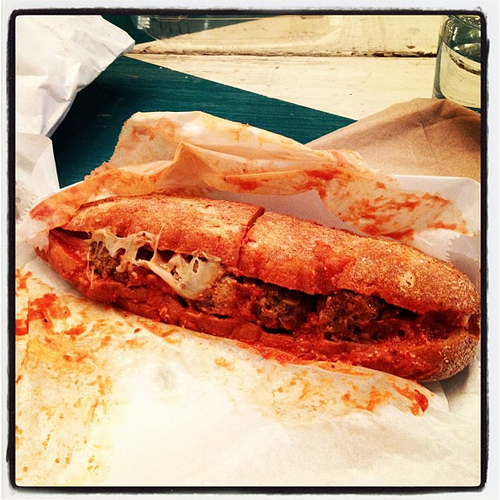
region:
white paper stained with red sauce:
[45, 95, 462, 236]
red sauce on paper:
[17, 299, 199, 451]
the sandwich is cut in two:
[36, 190, 483, 400]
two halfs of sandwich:
[31, 188, 481, 389]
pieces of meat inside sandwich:
[83, 242, 389, 342]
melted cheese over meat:
[90, 223, 231, 300]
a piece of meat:
[324, 288, 379, 348]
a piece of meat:
[248, 285, 306, 336]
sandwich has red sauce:
[68, 318, 440, 379]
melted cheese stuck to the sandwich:
[90, 219, 222, 294]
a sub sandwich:
[18, 178, 483, 403]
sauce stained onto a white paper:
[22, 91, 482, 483]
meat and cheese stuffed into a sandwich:
[51, 213, 461, 364]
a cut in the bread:
[222, 203, 293, 273]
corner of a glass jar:
[434, 15, 482, 118]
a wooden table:
[47, 18, 482, 179]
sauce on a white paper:
[18, 280, 448, 475]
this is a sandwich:
[35, 125, 454, 450]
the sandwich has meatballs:
[51, 177, 478, 424]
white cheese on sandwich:
[94, 213, 250, 310]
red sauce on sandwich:
[83, 201, 373, 390]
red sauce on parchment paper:
[22, 287, 169, 451]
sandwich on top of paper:
[52, 131, 457, 498]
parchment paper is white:
[62, 110, 443, 488]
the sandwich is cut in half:
[43, 145, 497, 422]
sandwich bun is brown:
[110, 178, 445, 320]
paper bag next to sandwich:
[282, 75, 474, 204]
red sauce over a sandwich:
[22, 180, 482, 380]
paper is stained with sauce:
[82, 105, 437, 210]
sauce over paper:
[16, 295, 102, 425]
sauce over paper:
[255, 370, 435, 435]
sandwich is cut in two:
[40, 186, 480, 381]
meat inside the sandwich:
[67, 228, 433, 359]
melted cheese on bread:
[82, 221, 224, 308]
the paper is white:
[21, 20, 133, 125]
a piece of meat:
[308, 293, 379, 344]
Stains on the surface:
[361, 47, 430, 62]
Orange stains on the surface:
[25, 293, 102, 363]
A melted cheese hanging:
[92, 227, 167, 272]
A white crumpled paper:
[350, 396, 467, 470]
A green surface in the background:
[108, 78, 193, 108]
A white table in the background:
[283, 67, 390, 90]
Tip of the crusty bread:
[442, 354, 474, 390]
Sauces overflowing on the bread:
[280, 315, 429, 380]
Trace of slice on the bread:
[240, 200, 282, 239]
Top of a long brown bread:
[351, 228, 466, 308]